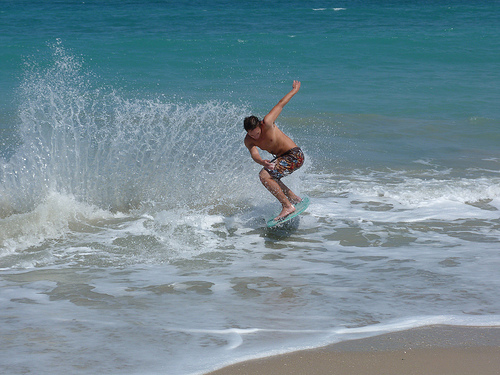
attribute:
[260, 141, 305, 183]
trunks — blue, brown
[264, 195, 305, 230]
board — blue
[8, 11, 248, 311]
water — turquoise, blue 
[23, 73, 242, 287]
waves — white, blue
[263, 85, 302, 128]
arm — raised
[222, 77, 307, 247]
man — young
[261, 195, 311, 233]
surfboard — Blue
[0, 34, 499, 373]
waves — white, blue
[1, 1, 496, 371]
ocean — white, blue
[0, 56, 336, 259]
wave — sheer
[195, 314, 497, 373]
sand — tan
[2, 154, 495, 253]
wave — white, blue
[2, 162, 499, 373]
seafoam — white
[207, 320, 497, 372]
beach — smooth, Tan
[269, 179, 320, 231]
surfboard — wooden, green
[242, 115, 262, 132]
hair — brunette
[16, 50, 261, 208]
water — spraying